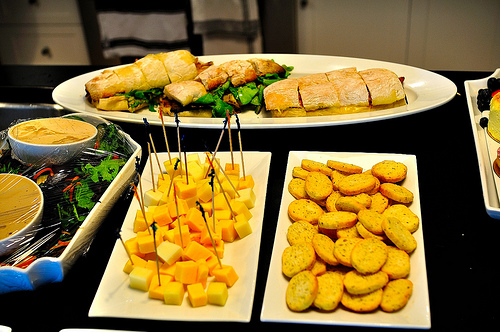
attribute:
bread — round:
[84, 49, 198, 112]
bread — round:
[162, 58, 285, 118]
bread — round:
[262, 66, 405, 115]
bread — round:
[302, 157, 333, 175]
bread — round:
[291, 166, 311, 181]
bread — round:
[329, 159, 362, 175]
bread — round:
[332, 170, 348, 191]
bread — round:
[370, 159, 407, 183]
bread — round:
[337, 174, 376, 195]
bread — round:
[288, 178, 306, 199]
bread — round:
[305, 171, 333, 200]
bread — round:
[381, 183, 415, 203]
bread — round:
[326, 191, 342, 212]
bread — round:
[287, 199, 324, 224]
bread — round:
[335, 197, 365, 213]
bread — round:
[353, 192, 372, 207]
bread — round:
[369, 193, 389, 211]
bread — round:
[382, 204, 420, 231]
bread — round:
[318, 208, 358, 231]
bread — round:
[357, 207, 387, 234]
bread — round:
[382, 216, 417, 253]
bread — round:
[355, 222, 384, 241]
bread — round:
[336, 225, 360, 239]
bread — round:
[286, 219, 317, 245]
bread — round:
[280, 242, 317, 275]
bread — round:
[312, 231, 339, 265]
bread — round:
[333, 237, 363, 265]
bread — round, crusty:
[351, 236, 388, 275]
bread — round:
[379, 246, 411, 280]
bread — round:
[311, 256, 327, 276]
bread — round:
[284, 271, 317, 311]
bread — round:
[314, 272, 344, 312]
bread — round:
[341, 268, 387, 295]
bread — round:
[377, 279, 413, 313]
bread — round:
[339, 290, 382, 313]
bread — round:
[370, 173, 380, 196]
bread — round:
[362, 167, 376, 177]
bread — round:
[325, 262, 352, 279]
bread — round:
[316, 199, 331, 212]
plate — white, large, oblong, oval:
[50, 51, 460, 131]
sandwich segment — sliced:
[248, 55, 288, 85]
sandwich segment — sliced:
[262, 78, 306, 120]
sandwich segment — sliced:
[296, 73, 342, 117]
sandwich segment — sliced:
[325, 66, 371, 114]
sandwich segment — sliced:
[360, 68, 406, 110]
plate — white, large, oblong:
[87, 149, 273, 323]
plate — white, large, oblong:
[0, 112, 142, 289]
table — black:
[1, 62, 498, 330]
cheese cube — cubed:
[176, 180, 196, 199]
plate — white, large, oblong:
[260, 150, 433, 329]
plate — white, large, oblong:
[462, 67, 499, 218]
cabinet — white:
[0, 1, 92, 67]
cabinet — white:
[297, 2, 498, 72]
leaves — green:
[119, 88, 163, 111]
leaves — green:
[193, 65, 292, 119]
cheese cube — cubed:
[188, 283, 206, 308]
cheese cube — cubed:
[128, 267, 155, 291]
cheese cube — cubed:
[175, 260, 198, 285]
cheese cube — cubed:
[185, 242, 212, 263]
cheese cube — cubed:
[206, 282, 229, 306]